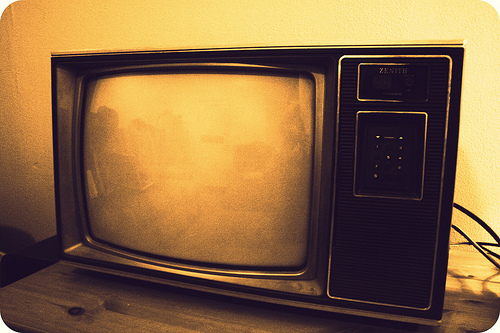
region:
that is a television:
[50, 41, 456, 297]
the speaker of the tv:
[359, 114, 428, 199]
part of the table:
[48, 282, 68, 309]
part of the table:
[142, 298, 187, 310]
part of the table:
[190, 317, 255, 332]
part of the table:
[6, 288, 33, 312]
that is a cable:
[464, 210, 494, 229]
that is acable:
[454, 227, 463, 254]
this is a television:
[95, 133, 320, 254]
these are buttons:
[278, 126, 454, 266]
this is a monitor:
[127, 156, 317, 244]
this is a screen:
[44, 196, 252, 308]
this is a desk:
[21, 272, 77, 330]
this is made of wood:
[55, 245, 157, 323]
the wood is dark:
[84, 329, 89, 330]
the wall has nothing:
[21, 109, 33, 166]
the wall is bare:
[9, 148, 54, 193]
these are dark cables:
[466, 162, 488, 274]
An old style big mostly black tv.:
[48, 40, 465, 330]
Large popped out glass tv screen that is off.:
[67, 67, 323, 277]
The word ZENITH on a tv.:
[377, 64, 410, 76]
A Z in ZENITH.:
[377, 65, 385, 74]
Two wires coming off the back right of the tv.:
[450, 202, 499, 266]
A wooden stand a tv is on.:
[0, 248, 498, 332]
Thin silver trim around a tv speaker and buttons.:
[326, 51, 453, 311]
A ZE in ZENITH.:
[377, 63, 389, 75]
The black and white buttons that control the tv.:
[364, 123, 419, 190]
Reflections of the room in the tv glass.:
[76, 77, 311, 257]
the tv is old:
[63, 35, 423, 330]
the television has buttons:
[355, 105, 425, 200]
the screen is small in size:
[94, 65, 295, 265]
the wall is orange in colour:
[77, 10, 222, 46]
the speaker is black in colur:
[334, 200, 421, 297]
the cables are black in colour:
[468, 195, 483, 294]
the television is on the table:
[45, 225, 453, 331]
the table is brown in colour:
[18, 267, 104, 323]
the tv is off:
[70, 64, 442, 331]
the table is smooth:
[41, 263, 168, 332]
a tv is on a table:
[24, 18, 482, 326]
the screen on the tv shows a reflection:
[81, 68, 321, 284]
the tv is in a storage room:
[77, 63, 321, 278]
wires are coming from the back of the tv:
[441, 192, 498, 283]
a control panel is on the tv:
[339, 55, 449, 271]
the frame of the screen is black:
[63, 55, 336, 292]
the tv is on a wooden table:
[0, 229, 492, 331]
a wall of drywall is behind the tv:
[5, 5, 498, 256]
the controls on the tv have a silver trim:
[323, 50, 454, 316]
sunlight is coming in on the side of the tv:
[341, 16, 499, 328]